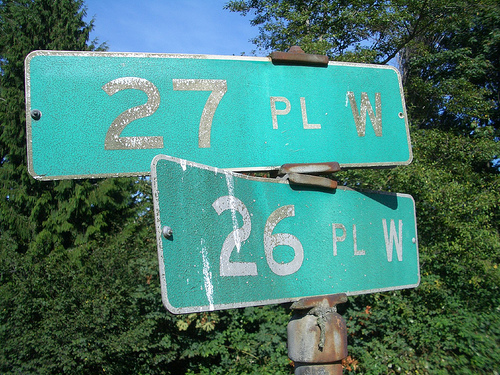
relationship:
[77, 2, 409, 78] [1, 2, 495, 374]
blue sky behind trees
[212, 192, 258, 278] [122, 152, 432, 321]
number on street sign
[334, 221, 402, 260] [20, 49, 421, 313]
letters on street sign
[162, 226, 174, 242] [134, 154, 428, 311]
screw holding sign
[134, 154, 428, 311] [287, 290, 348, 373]
sign on post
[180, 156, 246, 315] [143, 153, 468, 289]
bird droppings dried on sign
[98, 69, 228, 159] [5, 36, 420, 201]
number on sign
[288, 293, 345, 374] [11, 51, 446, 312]
pole holding signs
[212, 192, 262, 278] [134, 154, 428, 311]
number on sign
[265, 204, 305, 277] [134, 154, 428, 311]
number on sign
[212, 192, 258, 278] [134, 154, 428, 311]
number on sign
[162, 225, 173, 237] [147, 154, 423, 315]
bolt on sign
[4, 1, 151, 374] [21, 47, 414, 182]
tree behind sign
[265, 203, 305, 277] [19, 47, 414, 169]
number on sign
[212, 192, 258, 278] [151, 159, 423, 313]
number on sign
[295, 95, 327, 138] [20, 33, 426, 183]
letter on sign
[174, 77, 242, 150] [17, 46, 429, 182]
number on sign